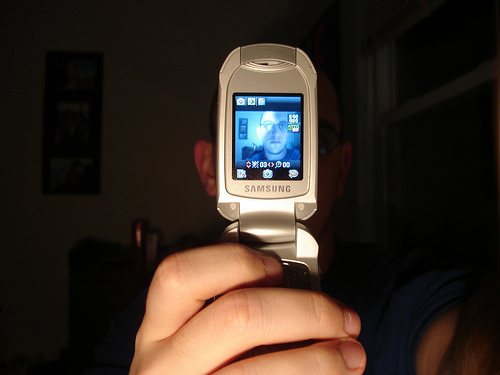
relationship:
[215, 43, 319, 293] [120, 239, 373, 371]
cell phone in hand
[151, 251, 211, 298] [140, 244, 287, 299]
knuckle on finger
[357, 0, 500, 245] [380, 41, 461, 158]
window with frame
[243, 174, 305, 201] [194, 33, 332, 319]
logo on phone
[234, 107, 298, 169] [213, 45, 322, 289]
picture on phone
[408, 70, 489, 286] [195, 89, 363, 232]
window behind man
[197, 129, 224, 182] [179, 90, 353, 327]
ears of owner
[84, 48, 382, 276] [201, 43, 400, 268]
cabinet behind man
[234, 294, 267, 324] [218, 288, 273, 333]
lines on knuckle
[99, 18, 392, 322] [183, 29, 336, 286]
man taking picture